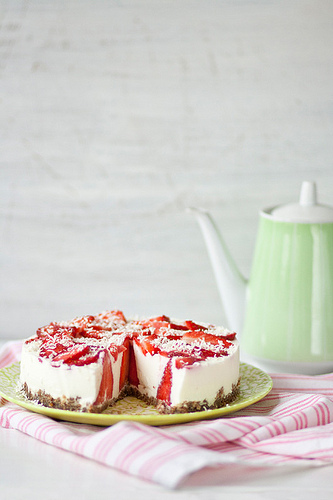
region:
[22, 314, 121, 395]
red and white slice of cheesecake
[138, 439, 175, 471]
pink and white napkin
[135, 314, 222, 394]
dessert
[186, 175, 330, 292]
green and white tea pot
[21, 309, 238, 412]
cheese cake with strawberries on top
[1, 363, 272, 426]
yellow and white platter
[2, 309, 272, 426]
cheese cake on a yellow and white plate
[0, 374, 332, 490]
red and pink table cloth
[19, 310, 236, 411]
red white and brown desert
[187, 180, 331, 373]
white and green kettle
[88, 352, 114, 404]
piece of red strawberry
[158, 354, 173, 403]
piece of red strawberry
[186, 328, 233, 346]
piece of red strawberry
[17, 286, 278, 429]
Cake is on a plate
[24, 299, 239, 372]
Slices of strawberries on top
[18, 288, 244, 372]
Slices of strawberry on top of the cake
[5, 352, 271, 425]
The plate has cake on it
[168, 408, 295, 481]
Towel under a plate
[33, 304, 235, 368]
An array of slices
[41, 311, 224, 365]
An array of strawberry slices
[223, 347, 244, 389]
pie on a plate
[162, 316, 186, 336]
pie on a plate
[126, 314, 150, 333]
pie on a plate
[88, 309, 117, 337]
pie on a plate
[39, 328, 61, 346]
pie on a plate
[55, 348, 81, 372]
pie on a plate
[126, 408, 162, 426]
plate on a napkin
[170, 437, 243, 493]
napkin on a plate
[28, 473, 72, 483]
clean blue table surface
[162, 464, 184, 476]
white portion of tablecloth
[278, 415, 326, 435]
red stripes on table cloth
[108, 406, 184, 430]
yellow plate holding cake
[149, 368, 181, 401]
strawberry in white cake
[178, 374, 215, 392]
cream surface of cake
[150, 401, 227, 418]
graham cracker crust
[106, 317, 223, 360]
white sprinkles on top of cake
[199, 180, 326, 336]
green and white jug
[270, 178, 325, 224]
white lid on green jug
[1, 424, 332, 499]
shiny white table top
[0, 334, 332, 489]
white tea towel with pink stripes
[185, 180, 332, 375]
light green and white tall teapot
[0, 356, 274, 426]
light green and white speckled dessert plate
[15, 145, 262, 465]
this is a dessert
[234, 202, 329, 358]
this is a kettle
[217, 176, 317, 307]
the kettle is green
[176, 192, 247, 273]
the spout is white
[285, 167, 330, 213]
the handle is white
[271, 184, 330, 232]
the lid is white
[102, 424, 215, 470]
the table cloth is red and white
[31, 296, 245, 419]
Cake on a plate